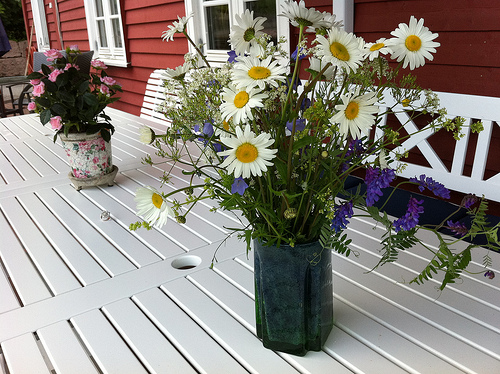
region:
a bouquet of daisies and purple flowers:
[129, 0, 496, 289]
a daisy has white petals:
[382, 14, 438, 69]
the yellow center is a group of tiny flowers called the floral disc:
[235, 141, 256, 159]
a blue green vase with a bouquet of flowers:
[250, 231, 330, 351]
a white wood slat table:
[0, 100, 496, 371]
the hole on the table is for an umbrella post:
[170, 255, 200, 269]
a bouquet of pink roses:
[25, 47, 121, 131]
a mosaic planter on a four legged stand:
[57, 122, 118, 188]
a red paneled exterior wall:
[21, 0, 498, 116]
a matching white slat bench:
[140, 68, 214, 124]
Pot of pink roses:
[23, 38, 125, 195]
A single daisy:
[125, 181, 183, 241]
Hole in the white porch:
[142, 244, 219, 303]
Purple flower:
[360, 166, 397, 218]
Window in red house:
[79, 6, 138, 69]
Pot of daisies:
[144, 11, 397, 358]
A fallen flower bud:
[92, 199, 119, 243]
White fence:
[448, 86, 499, 218]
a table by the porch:
[0, 49, 33, 129]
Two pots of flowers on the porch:
[19, 4, 441, 358]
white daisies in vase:
[136, 0, 439, 359]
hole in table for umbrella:
[168, 247, 208, 278]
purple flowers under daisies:
[326, 158, 457, 240]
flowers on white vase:
[55, 121, 127, 185]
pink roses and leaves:
[23, 39, 125, 129]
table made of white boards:
[51, 317, 214, 366]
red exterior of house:
[131, 9, 173, 59]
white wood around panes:
[85, 6, 134, 69]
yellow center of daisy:
[234, 143, 265, 165]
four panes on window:
[94, 0, 117, 50]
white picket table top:
[73, 256, 189, 354]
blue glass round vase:
[221, 234, 357, 355]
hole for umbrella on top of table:
[153, 238, 234, 294]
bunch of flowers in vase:
[153, 26, 431, 252]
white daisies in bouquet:
[212, 49, 290, 185]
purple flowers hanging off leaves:
[328, 149, 484, 253]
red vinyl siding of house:
[134, 14, 184, 60]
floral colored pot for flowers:
[56, 124, 130, 187]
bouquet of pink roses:
[26, 57, 135, 151]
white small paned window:
[78, 11, 148, 50]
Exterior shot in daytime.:
[7, 0, 497, 359]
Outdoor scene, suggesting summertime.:
[8, 14, 475, 371]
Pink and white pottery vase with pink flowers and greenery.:
[24, 23, 119, 195]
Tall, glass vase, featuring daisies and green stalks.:
[156, 1, 358, 351]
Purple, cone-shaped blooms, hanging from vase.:
[346, 150, 498, 292]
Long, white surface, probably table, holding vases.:
[10, 96, 496, 349]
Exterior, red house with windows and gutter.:
[25, 0, 495, 86]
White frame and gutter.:
[30, 1, 141, 71]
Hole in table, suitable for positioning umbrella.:
[173, 250, 198, 277]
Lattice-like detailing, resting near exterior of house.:
[381, 97, 496, 206]